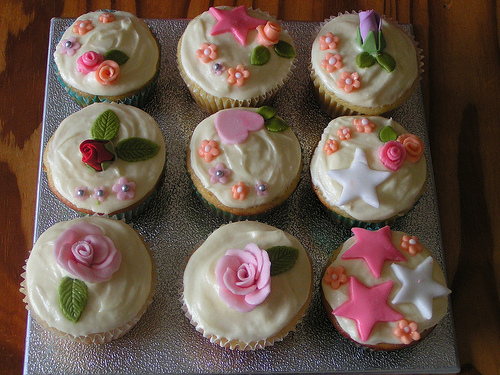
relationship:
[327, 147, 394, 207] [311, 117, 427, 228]
star on cupcake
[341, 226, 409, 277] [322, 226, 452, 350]
star on cupcake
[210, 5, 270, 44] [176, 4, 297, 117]
star on cupcake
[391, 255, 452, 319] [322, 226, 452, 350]
star on cupcake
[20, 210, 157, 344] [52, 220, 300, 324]
cupcake have rose designs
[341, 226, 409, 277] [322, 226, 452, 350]
star on top of cupcake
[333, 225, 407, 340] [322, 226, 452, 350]
two stars are on cupcake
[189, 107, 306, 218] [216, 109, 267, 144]
cupcake has a heart design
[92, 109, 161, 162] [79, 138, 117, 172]
leaves are a part of rose design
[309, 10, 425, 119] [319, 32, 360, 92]
cupcake has a floral design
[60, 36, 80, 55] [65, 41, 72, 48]
pink flower has a silver bead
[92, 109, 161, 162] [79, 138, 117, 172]
leaves are next to a rose design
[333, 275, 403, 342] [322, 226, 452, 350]
fondant on top of a cupcake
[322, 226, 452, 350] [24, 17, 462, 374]
cupcake on tray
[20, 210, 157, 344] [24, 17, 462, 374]
cupcake are on a tray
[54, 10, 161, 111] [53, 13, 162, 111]
cupcake has a wrapper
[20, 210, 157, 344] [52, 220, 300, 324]
cupcake have floral design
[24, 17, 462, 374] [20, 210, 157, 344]
tray has cupcake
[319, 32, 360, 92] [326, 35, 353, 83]
floral design has pearl centers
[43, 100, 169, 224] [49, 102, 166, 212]
cupcake has icing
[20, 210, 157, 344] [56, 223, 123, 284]
cupcake has a pink flower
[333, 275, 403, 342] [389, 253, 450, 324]
star next to star